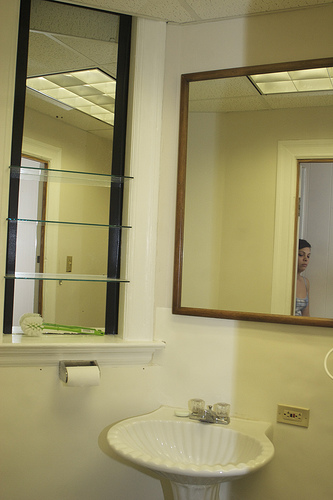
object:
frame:
[173, 58, 331, 328]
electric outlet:
[275, 403, 310, 429]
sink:
[106, 403, 275, 499]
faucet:
[186, 404, 229, 425]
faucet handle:
[188, 395, 205, 419]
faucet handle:
[214, 402, 231, 417]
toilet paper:
[65, 366, 99, 388]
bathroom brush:
[22, 314, 106, 339]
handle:
[45, 325, 109, 337]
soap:
[172, 407, 190, 419]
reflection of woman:
[293, 238, 311, 322]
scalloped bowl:
[120, 419, 263, 469]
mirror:
[12, 1, 121, 336]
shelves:
[4, 164, 133, 284]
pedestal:
[160, 482, 228, 499]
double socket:
[283, 410, 305, 420]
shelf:
[6, 313, 128, 347]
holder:
[58, 360, 104, 388]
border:
[7, 2, 138, 343]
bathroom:
[0, 1, 333, 498]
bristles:
[20, 313, 44, 337]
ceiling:
[27, 0, 120, 151]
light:
[26, 70, 116, 124]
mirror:
[181, 54, 333, 322]